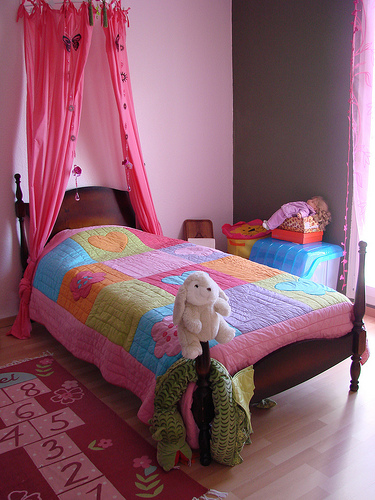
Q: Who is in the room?
A: No one.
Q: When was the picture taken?
A: During the day.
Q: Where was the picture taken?
A: In a room.